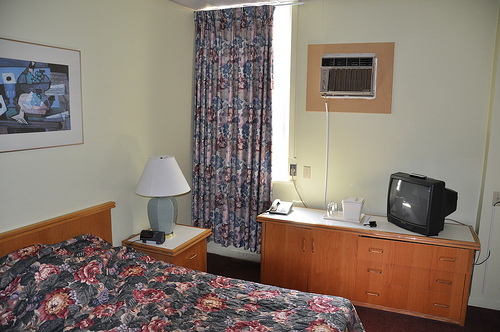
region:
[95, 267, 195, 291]
the bed is made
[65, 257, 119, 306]
the blanket has flowers on it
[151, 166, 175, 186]
the shade is white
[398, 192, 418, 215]
the tv is off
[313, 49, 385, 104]
the ac is in the wall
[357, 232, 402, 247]
the drawer is cracked open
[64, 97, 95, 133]
the picture is on the wall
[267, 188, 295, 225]
the phone is by the window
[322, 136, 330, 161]
the cord is white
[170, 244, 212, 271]
the stand is brown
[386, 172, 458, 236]
small black tv on stand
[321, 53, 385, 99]
air conditioner on wall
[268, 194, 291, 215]
cord phone on stand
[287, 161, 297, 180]
electrical outlet on wall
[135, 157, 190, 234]
lamp sitting on stand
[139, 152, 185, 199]
a white lamp shade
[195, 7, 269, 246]
floral pattern drapes on window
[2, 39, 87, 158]
painting on the wall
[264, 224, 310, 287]
wooden cabinet on stand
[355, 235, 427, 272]
brown drawer on stand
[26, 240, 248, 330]
Floral prints in bedsheet.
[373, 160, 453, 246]
TV is black color.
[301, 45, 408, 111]
AC is fixed to the wall.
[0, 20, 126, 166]
Picture is hanging in wall.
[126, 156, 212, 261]
Lamp is in side table.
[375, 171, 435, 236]
Reflection is seen in the screen.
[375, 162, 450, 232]
TV screen is off.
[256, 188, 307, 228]
Phone is white color.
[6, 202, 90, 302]
Cot is brown color.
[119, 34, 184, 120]
Wall is white color.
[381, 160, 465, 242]
a TV in a hotel room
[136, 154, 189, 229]
a lamp in a hotel room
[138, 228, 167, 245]
an alarm clock radio in a hotel room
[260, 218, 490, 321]
a dresser in a hotel room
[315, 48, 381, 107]
an air-conditioner in a hotel room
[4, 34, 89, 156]
a picture in a hotel room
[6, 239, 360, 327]
a bed in a hotel room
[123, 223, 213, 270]
a night stand in a hotel room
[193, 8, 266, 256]
a curtain in a hotel room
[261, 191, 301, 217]
a phone in a hotel room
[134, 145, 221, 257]
a lamp in a room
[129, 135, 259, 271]
a lamp on a night stand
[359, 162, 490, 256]
a tv on a dresser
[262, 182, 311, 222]
a phone on a dresser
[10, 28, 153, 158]
a picture on a wall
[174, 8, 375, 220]
curtains on a window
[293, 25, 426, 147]
a air conditioner in a room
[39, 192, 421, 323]
a blanket on a bed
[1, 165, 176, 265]
the headboard on a bed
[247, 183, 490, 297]
a dresser in a room